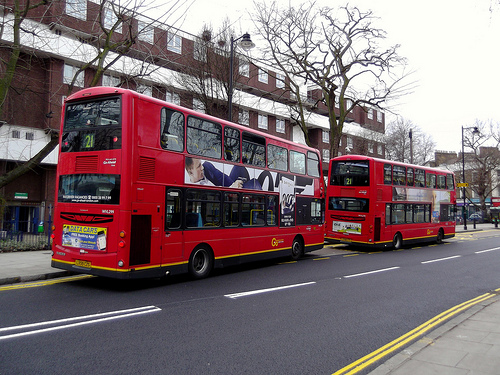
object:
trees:
[253, 1, 407, 225]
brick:
[154, 49, 160, 52]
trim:
[1, 6, 386, 145]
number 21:
[83, 133, 99, 150]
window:
[59, 60, 88, 87]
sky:
[92, 0, 500, 155]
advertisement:
[185, 155, 317, 200]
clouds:
[106, 0, 500, 158]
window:
[272, 72, 296, 92]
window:
[254, 111, 274, 132]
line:
[339, 263, 408, 281]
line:
[419, 253, 462, 265]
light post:
[458, 122, 483, 230]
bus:
[324, 149, 458, 252]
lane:
[0, 226, 500, 374]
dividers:
[223, 278, 322, 304]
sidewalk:
[361, 294, 500, 374]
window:
[258, 66, 278, 84]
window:
[236, 56, 252, 80]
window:
[164, 31, 187, 57]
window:
[61, 0, 93, 24]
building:
[419, 146, 500, 223]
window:
[59, 91, 125, 151]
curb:
[364, 291, 500, 375]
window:
[234, 103, 251, 127]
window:
[320, 127, 335, 145]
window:
[190, 95, 208, 116]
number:
[84, 135, 91, 150]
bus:
[51, 82, 329, 283]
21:
[344, 176, 357, 185]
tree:
[456, 123, 500, 222]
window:
[135, 19, 158, 44]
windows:
[161, 105, 186, 158]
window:
[192, 40, 212, 66]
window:
[55, 170, 121, 204]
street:
[0, 228, 500, 373]